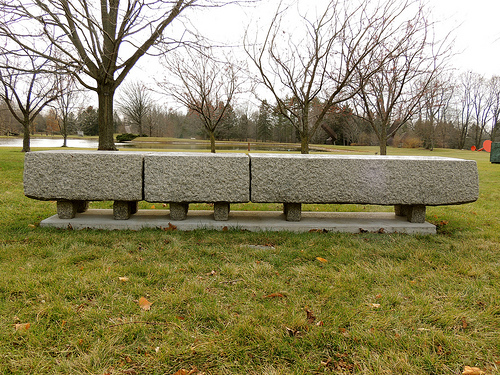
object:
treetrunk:
[98, 88, 120, 151]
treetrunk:
[21, 107, 31, 151]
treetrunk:
[208, 127, 215, 153]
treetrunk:
[298, 103, 313, 154]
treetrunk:
[376, 126, 388, 156]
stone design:
[24, 149, 480, 237]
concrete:
[21, 150, 478, 235]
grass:
[0, 135, 498, 375]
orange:
[308, 269, 415, 329]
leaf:
[0, 223, 500, 375]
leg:
[56, 200, 75, 220]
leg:
[72, 201, 89, 213]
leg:
[113, 201, 131, 220]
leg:
[213, 201, 230, 221]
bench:
[21, 150, 479, 223]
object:
[483, 137, 495, 154]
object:
[470, 145, 476, 151]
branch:
[118, 5, 193, 86]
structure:
[282, 166, 342, 199]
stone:
[22, 148, 479, 233]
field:
[1, 132, 500, 375]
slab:
[341, 211, 436, 237]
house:
[113, 111, 139, 133]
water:
[0, 135, 357, 152]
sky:
[0, 0, 500, 129]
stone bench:
[20, 149, 480, 237]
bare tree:
[241, 0, 448, 153]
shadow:
[286, 217, 399, 237]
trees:
[0, 0, 500, 152]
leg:
[283, 202, 302, 221]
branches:
[245, 27, 372, 106]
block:
[23, 149, 480, 234]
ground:
[0, 128, 500, 375]